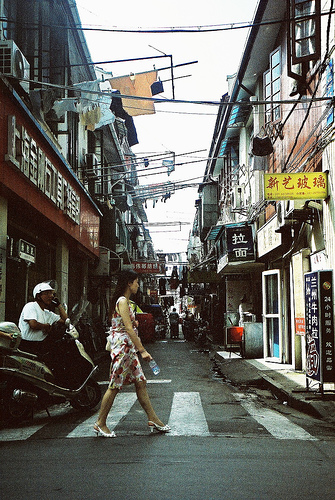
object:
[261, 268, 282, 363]
door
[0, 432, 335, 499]
pavement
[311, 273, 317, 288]
character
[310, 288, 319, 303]
character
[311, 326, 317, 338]
character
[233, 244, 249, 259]
character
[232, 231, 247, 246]
character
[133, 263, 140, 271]
character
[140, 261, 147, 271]
character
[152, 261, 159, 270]
character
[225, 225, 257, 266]
sign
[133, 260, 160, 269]
sign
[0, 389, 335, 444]
crosswalk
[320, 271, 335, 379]
foreing character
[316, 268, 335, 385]
sign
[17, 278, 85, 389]
man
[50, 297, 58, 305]
cell phone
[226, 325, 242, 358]
orange chair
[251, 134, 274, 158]
clothesline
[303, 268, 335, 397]
bus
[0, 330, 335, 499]
sidewalk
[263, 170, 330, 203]
sign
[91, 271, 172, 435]
woman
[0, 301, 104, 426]
motorcycle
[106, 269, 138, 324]
hair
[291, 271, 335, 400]
sign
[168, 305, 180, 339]
woman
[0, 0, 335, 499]
alley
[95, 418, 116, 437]
dress shoes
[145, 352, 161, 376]
bottle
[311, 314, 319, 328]
character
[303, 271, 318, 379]
foreign character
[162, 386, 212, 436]
line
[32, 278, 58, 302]
helmet